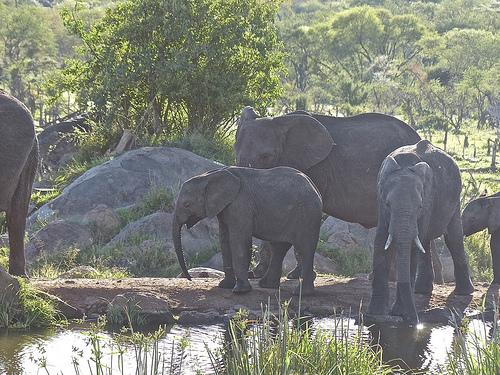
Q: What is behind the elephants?
A: A gray boulder.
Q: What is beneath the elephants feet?
A: A dirt path.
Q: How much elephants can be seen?
A: 5.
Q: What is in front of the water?
A: Patch of tall grass.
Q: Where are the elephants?
A: Out in the wild.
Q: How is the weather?
A: Bright and sunny.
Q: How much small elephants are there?
A: Two.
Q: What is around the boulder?
A: Grass.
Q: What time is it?
A: Afternoon.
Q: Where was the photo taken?
A: Outside somewhere.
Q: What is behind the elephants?
A: Large boulders.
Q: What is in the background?
A: Many trees.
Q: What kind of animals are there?
A: Elephants.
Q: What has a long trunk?
A: The elephant.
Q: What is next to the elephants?
A: Water.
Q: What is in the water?
A: A reflection.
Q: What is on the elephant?
A: Tusks.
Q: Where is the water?
A: In front of the elephants.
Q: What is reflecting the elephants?
A: Water.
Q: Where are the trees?
A: Behind the animals.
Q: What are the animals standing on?
A: Dirt.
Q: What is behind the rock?
A: Large tree.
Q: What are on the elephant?
A: Tusks.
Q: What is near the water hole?
A: Grass.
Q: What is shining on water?
A: Sun.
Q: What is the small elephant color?
A: Grey.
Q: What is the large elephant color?
A: Grey.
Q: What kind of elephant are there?
A: Large grey.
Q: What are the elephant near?
A: Water.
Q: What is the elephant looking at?
A: The camera.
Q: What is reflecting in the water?
A: Sunlight.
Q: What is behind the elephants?
A: A rock pile.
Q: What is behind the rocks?
A: A tree.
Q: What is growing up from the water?
A: Weeds.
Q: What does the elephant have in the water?
A: It's trunk.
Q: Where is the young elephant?
A: Beside its mother.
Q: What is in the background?
A: Trees.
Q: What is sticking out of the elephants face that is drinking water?
A: Tusks.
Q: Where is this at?
A: In a zoo.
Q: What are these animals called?
A: Elephants.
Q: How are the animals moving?
A: Walking.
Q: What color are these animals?
A: Gray.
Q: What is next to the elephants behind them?
A: A rock.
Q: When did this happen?
A: During the day.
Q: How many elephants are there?
A: Five.